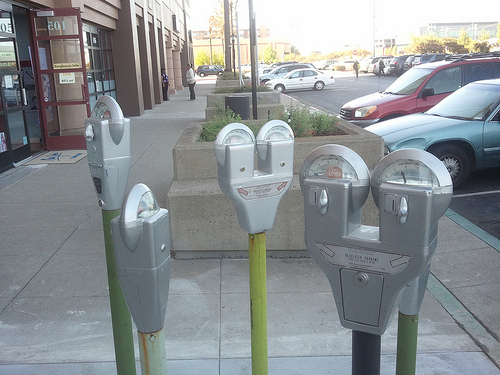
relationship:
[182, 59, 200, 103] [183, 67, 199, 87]
woman wearing sweater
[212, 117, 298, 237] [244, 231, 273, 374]
meter has pole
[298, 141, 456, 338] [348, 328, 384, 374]
meter has pole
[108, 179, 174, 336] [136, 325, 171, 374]
meter has pole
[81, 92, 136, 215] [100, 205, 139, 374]
meter has pole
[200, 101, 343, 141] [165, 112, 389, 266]
plants in planter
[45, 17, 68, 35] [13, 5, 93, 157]
number on door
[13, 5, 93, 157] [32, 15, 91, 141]
door has glass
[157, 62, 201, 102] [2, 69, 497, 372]
women on sidewalk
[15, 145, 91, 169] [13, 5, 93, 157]
mat outside door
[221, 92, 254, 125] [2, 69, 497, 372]
trash can on sidewalk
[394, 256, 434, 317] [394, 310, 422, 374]
meter has pole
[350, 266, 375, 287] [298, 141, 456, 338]
lock on meter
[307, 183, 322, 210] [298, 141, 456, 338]
slot on meter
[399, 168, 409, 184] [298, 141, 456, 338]
arrow on meter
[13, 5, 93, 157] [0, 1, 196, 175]
door on building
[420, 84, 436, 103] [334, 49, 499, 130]
mirror on vehicle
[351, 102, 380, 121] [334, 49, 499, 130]
headlight on vehicle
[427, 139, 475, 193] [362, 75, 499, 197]
wheel on vehicle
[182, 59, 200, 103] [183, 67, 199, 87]
person wearing shirt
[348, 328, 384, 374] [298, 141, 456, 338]
pole of parking meter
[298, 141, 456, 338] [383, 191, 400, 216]
meter has slot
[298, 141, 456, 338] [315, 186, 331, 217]
meter has knob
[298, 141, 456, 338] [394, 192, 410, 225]
meter has knob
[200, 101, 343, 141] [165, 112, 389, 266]
bushes in box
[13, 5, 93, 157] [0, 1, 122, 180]
door to business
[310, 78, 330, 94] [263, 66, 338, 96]
wheel on car